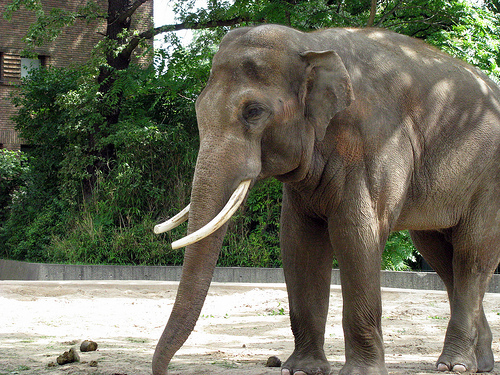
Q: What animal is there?
A: Elephant.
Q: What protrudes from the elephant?
A: Tusks.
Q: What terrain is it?
A: Dirt.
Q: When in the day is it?
A: Afternoon.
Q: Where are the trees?
A: Background.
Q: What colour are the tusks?
A: White.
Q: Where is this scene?
A: Zoo.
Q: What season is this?
A: Summer.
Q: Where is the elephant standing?
A: In the dirt.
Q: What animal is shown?
A: An elephant.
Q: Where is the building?
A: Behind the elephant.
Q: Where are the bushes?
A: Lining the dirt patch.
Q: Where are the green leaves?
A: On the bushes.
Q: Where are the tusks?
A: On the elephants.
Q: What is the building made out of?
A: Brick.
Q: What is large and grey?
A: The elephant.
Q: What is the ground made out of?
A: Sand.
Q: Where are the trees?
A: In the distance.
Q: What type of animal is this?
A: An elephant.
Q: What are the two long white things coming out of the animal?
A: Ivory tusks.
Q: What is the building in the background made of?
A: Red brick.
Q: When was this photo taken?
A: Daytime.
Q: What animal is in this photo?
A: Elephant.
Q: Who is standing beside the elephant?
A: No one.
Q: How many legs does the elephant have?
A: Four.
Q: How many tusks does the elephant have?
A: Two.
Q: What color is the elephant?
A: Grey.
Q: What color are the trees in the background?
A: Green.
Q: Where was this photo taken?
A: At a zoo.